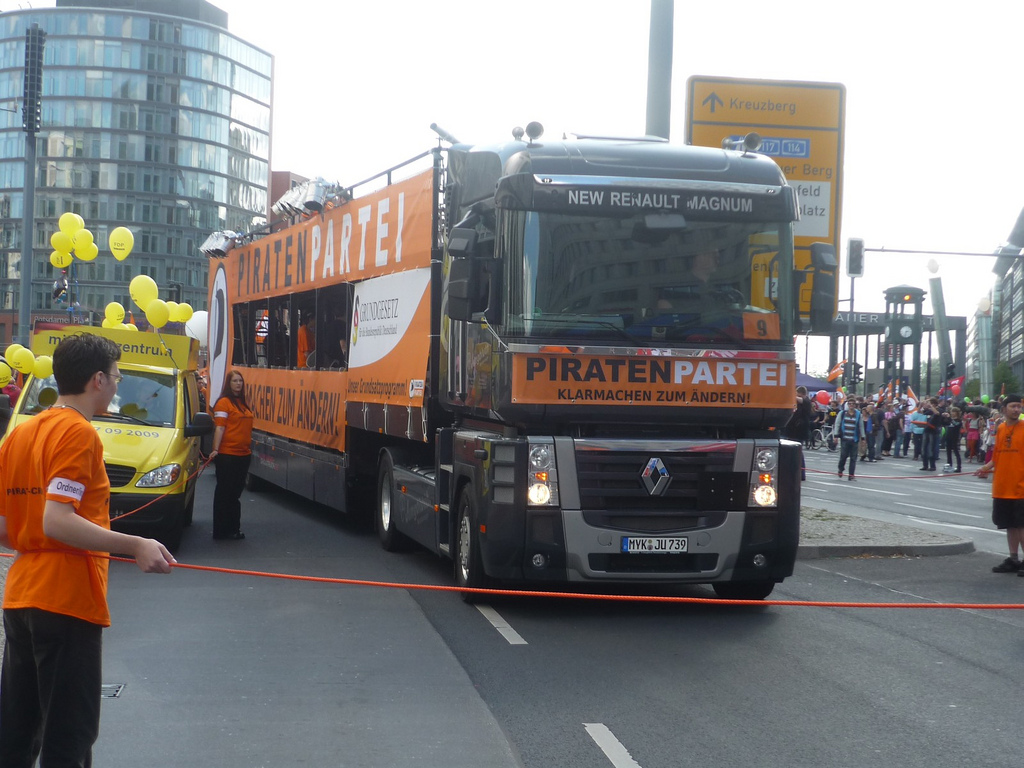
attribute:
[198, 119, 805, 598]
bus — large, orange and black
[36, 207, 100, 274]
yellow balloons — yellow 